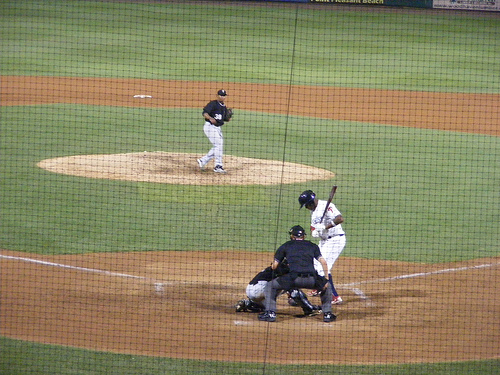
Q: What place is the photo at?
A: It is at the field.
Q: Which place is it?
A: It is a field.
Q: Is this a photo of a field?
A: Yes, it is showing a field.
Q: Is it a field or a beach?
A: It is a field.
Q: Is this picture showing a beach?
A: No, the picture is showing a field.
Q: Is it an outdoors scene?
A: Yes, it is outdoors.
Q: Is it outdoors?
A: Yes, it is outdoors.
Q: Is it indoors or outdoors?
A: It is outdoors.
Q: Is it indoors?
A: No, it is outdoors.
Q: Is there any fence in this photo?
A: Yes, there is a fence.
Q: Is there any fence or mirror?
A: Yes, there is a fence.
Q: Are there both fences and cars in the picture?
A: No, there is a fence but no cars.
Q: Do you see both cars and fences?
A: No, there is a fence but no cars.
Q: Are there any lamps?
A: No, there are no lamps.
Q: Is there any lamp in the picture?
A: No, there are no lamps.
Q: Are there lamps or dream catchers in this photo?
A: No, there are no lamps or dream catchers.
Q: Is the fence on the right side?
A: Yes, the fence is on the right of the image.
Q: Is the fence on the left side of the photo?
A: No, the fence is on the right of the image.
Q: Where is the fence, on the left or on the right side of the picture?
A: The fence is on the right of the image.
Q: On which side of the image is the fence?
A: The fence is on the right of the image.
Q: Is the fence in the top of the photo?
A: Yes, the fence is in the top of the image.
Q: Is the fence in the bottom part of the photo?
A: No, the fence is in the top of the image.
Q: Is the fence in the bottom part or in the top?
A: The fence is in the top of the image.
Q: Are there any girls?
A: No, there are no girls.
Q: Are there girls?
A: No, there are no girls.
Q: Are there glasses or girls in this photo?
A: No, there are no girls or glasses.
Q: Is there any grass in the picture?
A: Yes, there is grass.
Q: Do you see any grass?
A: Yes, there is grass.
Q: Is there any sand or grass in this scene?
A: Yes, there is grass.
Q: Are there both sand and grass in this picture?
A: No, there is grass but no sand.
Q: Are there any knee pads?
A: No, there are no knee pads.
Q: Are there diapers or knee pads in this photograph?
A: No, there are no knee pads or diapers.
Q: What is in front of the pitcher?
A: The grass is in front of the pitcher.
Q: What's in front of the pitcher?
A: The grass is in front of the pitcher.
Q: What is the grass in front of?
A: The grass is in front of the pitcher.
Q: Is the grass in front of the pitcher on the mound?
A: Yes, the grass is in front of the pitcher.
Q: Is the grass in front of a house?
A: No, the grass is in front of the pitcher.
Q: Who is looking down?
A: The player is looking down.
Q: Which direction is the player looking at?
A: The player is looking down.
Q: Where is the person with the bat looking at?
A: The player is looking down.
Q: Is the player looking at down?
A: Yes, the player is looking down.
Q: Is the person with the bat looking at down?
A: Yes, the player is looking down.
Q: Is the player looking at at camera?
A: No, the player is looking down.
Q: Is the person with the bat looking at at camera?
A: No, the player is looking down.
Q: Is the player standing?
A: Yes, the player is standing.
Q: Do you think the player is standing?
A: Yes, the player is standing.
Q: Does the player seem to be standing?
A: Yes, the player is standing.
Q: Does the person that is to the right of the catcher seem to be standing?
A: Yes, the player is standing.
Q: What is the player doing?
A: The player is standing.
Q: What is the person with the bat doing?
A: The player is standing.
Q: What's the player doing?
A: The player is standing.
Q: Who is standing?
A: The player is standing.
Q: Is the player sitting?
A: No, the player is standing.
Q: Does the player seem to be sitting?
A: No, the player is standing.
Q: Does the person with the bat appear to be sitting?
A: No, the player is standing.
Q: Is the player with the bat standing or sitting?
A: The player is standing.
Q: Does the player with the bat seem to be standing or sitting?
A: The player is standing.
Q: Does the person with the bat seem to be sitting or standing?
A: The player is standing.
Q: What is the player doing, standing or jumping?
A: The player is standing.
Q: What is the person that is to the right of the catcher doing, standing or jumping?
A: The player is standing.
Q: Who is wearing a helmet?
A: The player is wearing a helmet.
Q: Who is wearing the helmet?
A: The player is wearing a helmet.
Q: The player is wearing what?
A: The player is wearing a helmet.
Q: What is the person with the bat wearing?
A: The player is wearing a helmet.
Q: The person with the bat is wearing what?
A: The player is wearing a helmet.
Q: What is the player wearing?
A: The player is wearing a helmet.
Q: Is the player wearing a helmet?
A: Yes, the player is wearing a helmet.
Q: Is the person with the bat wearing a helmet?
A: Yes, the player is wearing a helmet.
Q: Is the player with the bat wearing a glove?
A: No, the player is wearing a helmet.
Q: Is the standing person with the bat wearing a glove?
A: No, the player is wearing a helmet.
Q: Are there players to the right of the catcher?
A: Yes, there is a player to the right of the catcher.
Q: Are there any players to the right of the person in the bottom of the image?
A: Yes, there is a player to the right of the catcher.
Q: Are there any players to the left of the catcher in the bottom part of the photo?
A: No, the player is to the right of the catcher.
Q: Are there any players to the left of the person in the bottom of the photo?
A: No, the player is to the right of the catcher.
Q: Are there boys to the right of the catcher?
A: No, there is a player to the right of the catcher.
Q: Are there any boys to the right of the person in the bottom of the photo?
A: No, there is a player to the right of the catcher.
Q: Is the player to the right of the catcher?
A: Yes, the player is to the right of the catcher.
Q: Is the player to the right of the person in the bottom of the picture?
A: Yes, the player is to the right of the catcher.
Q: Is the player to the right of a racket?
A: No, the player is to the right of the catcher.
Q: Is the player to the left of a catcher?
A: No, the player is to the right of a catcher.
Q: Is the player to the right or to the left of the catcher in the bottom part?
A: The player is to the right of the catcher.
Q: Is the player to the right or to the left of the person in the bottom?
A: The player is to the right of the catcher.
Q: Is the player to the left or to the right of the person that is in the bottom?
A: The player is to the right of the catcher.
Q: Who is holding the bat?
A: The player is holding the bat.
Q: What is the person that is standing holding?
A: The player is holding the bat.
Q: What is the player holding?
A: The player is holding the bat.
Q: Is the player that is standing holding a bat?
A: Yes, the player is holding a bat.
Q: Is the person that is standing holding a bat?
A: Yes, the player is holding a bat.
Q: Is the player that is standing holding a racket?
A: No, the player is holding a bat.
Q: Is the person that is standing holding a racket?
A: No, the player is holding a bat.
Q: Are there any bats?
A: Yes, there is a bat.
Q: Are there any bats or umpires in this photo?
A: Yes, there is a bat.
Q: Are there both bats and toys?
A: No, there is a bat but no toys.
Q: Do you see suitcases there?
A: No, there are no suitcases.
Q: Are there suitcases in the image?
A: No, there are no suitcases.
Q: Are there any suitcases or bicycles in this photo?
A: No, there are no suitcases or bicycles.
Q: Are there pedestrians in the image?
A: No, there are no pedestrians.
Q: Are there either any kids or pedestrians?
A: No, there are no pedestrians or kids.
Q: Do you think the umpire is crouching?
A: Yes, the umpire is crouching.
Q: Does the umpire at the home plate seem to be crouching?
A: Yes, the umpire is crouching.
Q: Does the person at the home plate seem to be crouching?
A: Yes, the umpire is crouching.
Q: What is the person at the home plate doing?
A: The umpire is crouching.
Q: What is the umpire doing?
A: The umpire is crouching.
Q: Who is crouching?
A: The umpire is crouching.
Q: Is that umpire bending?
A: No, the umpire is crouching.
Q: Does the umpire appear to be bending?
A: No, the umpire is crouching.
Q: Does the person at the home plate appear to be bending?
A: No, the umpire is crouching.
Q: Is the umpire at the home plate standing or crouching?
A: The umpire is crouching.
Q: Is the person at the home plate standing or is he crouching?
A: The umpire is crouching.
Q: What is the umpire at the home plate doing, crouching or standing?
A: The umpire is crouching.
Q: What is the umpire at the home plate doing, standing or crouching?
A: The umpire is crouching.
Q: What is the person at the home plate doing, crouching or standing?
A: The umpire is crouching.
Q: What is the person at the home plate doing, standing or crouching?
A: The umpire is crouching.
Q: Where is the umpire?
A: The umpire is at the home plate.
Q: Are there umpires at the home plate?
A: Yes, there is an umpire at the home plate.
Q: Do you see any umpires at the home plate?
A: Yes, there is an umpire at the home plate.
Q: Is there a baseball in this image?
A: Yes, there is a baseball.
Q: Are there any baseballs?
A: Yes, there is a baseball.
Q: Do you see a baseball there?
A: Yes, there is a baseball.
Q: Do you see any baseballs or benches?
A: Yes, there is a baseball.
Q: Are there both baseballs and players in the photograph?
A: Yes, there are both a baseball and a player.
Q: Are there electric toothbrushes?
A: No, there are no electric toothbrushes.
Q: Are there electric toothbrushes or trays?
A: No, there are no electric toothbrushes or trays.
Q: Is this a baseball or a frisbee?
A: This is a baseball.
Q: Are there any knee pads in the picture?
A: No, there are no knee pads.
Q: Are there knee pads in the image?
A: No, there are no knee pads.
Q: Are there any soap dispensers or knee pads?
A: No, there are no knee pads or soap dispensers.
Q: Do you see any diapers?
A: No, there are no diapers.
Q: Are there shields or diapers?
A: No, there are no diapers or shields.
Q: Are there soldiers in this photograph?
A: No, there are no soldiers.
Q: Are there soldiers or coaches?
A: No, there are no soldiers or coaches.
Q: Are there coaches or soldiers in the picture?
A: No, there are no soldiers or coaches.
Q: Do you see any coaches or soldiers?
A: No, there are no soldiers or coaches.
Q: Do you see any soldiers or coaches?
A: No, there are no soldiers or coaches.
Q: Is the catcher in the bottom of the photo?
A: Yes, the catcher is in the bottom of the image.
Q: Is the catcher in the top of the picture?
A: No, the catcher is in the bottom of the image.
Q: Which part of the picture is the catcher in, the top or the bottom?
A: The catcher is in the bottom of the image.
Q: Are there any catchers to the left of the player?
A: Yes, there is a catcher to the left of the player.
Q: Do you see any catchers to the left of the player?
A: Yes, there is a catcher to the left of the player.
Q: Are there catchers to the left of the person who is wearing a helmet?
A: Yes, there is a catcher to the left of the player.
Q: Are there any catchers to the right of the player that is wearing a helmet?
A: No, the catcher is to the left of the player.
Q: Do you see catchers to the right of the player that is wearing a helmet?
A: No, the catcher is to the left of the player.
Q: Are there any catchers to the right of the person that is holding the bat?
A: No, the catcher is to the left of the player.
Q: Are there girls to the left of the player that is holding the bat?
A: No, there is a catcher to the left of the player.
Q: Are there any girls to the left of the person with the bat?
A: No, there is a catcher to the left of the player.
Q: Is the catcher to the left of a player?
A: Yes, the catcher is to the left of a player.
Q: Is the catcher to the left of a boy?
A: No, the catcher is to the left of a player.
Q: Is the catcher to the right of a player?
A: No, the catcher is to the left of a player.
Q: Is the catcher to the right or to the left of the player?
A: The catcher is to the left of the player.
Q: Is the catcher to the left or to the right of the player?
A: The catcher is to the left of the player.